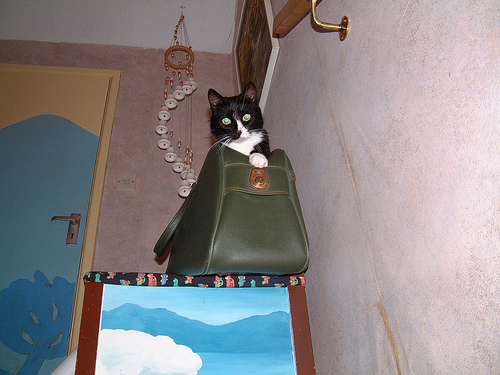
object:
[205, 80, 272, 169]
cat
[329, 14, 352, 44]
fixture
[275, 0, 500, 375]
wall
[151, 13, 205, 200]
chime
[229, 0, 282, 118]
frame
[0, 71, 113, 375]
door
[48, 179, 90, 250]
knob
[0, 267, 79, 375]
tree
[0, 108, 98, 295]
mountain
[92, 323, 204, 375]
cloud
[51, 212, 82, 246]
handle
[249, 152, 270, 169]
foot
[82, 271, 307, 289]
blanket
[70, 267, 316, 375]
table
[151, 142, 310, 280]
bag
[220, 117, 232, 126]
eye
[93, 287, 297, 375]
scenery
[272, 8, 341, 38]
lamp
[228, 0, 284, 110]
painting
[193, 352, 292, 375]
water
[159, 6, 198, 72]
object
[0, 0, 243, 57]
ceiling